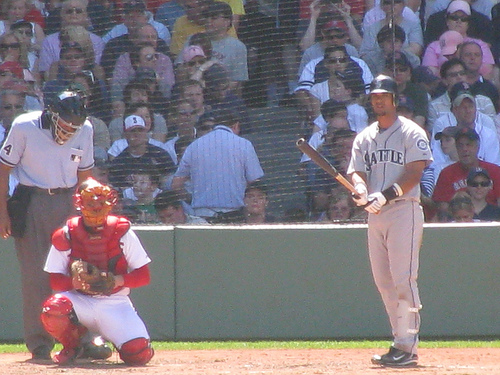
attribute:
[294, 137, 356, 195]
bat — brown, two-toned, pointed upwards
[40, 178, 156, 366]
catcher — wearing red, whit, kneeling down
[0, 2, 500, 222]
people — watching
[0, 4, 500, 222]
net — here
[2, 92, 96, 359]
umpire — looking down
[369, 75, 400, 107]
helmet — black in color, black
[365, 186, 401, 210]
glove — black, white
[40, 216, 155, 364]
uniform — red, white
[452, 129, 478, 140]
hat — blue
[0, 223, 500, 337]
wall — green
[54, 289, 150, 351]
pants — white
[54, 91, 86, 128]
helmet — protective, black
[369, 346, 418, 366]
shoes — nike brand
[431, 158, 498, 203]
shirt — red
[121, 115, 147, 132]
hat — red, white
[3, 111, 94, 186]
shirt — grey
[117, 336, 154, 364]
knee pad — red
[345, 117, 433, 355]
uniform — grey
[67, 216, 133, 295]
protective gear — red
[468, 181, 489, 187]
sunglasses — black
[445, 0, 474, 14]
hat — pink